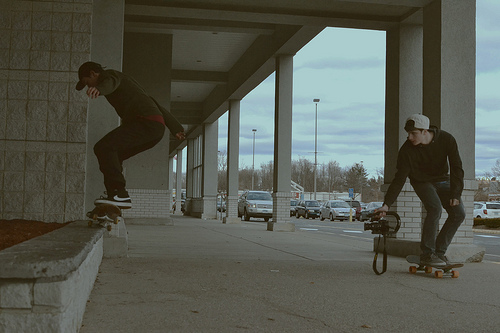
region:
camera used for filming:
[358, 202, 416, 291]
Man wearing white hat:
[396, 107, 435, 156]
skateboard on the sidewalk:
[399, 238, 482, 291]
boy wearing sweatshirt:
[365, 106, 473, 284]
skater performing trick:
[70, 58, 190, 230]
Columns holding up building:
[266, 48, 308, 258]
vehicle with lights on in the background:
[233, 181, 286, 239]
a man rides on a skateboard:
[73, 57, 185, 242]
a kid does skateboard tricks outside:
[69, 48, 197, 252]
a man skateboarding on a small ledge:
[72, 55, 199, 245]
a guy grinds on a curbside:
[69, 54, 194, 234]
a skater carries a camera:
[357, 108, 485, 289]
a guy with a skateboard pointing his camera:
[359, 113, 481, 285]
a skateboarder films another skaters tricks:
[63, 51, 473, 295]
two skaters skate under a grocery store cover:
[65, 55, 480, 290]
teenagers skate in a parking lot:
[63, 51, 473, 293]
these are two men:
[22, 35, 463, 242]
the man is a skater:
[50, 27, 192, 214]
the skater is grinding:
[52, 124, 247, 319]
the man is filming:
[354, 51, 489, 291]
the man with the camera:
[360, 200, 481, 284]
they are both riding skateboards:
[50, 193, 480, 298]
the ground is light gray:
[171, 234, 342, 311]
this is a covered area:
[102, 34, 334, 108]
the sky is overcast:
[292, 65, 376, 150]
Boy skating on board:
[344, 107, 497, 317]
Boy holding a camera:
[353, 193, 415, 303]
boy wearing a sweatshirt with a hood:
[355, 123, 490, 301]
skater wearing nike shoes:
[85, 168, 158, 225]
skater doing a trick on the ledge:
[67, 38, 202, 240]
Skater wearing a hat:
[68, 55, 126, 106]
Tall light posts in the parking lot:
[310, 84, 328, 239]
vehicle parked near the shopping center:
[223, 174, 287, 230]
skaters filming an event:
[49, 48, 492, 298]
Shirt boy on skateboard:
[71, 59, 186, 231]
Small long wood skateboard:
[88, 205, 121, 234]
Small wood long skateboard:
[405, 253, 465, 279]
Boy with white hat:
[375, 112, 466, 287]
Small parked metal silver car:
[235, 187, 273, 221]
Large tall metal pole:
[311, 96, 321, 200]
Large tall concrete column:
[266, 52, 297, 229]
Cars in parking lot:
[295, 194, 381, 224]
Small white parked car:
[471, 201, 498, 225]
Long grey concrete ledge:
[0, 217, 109, 332]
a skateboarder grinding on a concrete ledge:
[2, 67, 169, 330]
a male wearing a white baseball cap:
[392, 111, 432, 131]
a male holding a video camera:
[360, 208, 402, 243]